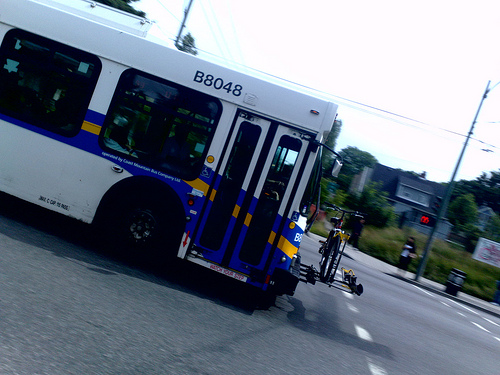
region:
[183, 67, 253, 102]
bus number on the side of the bus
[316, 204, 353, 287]
bike on the front of the bus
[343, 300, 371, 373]
white lines on the pavement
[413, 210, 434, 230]
pedestrian crossing sign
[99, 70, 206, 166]
window at the front of the bus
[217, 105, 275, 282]
doors on the bus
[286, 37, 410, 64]
sky is almost white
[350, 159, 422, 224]
buildings behind the sidewalk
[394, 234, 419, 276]
person is waiting at the corner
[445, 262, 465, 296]
paper box on the sidewalk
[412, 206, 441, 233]
cross walk signal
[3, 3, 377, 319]
bus driving down street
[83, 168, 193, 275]
front right bus wheel and tire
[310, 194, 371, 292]
bicycle on front of bus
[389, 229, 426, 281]
pedestrian waiting to cross street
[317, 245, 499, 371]
white stripes of cross walk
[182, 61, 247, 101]
bus ID number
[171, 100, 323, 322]
entry exit doors on bus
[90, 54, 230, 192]
window near front of bus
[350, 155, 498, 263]
house on side of street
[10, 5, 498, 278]
public transportation on a city street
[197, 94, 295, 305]
the door on the bus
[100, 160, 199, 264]
the wheel on the bus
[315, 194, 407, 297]
a bike rack on the bus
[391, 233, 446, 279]
a pedestrian waiting to cross the street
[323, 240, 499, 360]
a crosswalk for the person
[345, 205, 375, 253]
a person in the background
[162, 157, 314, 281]
the bus is yellow and blue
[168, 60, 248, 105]
the bus's ID number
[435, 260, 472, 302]
a stand near the corner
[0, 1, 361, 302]
A white, blue, and yellow bus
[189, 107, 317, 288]
A folding bus door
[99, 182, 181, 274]
The front tire of a bus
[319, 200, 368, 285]
A bike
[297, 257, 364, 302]
A bus rack on the front of a bus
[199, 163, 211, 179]
A blue and white handicap sign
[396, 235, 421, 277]
A person waiting to cross the street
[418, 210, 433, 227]
A cross walk signal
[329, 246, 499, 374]
A cross walk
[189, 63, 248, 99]
A bus identification number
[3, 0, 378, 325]
A bus in the foreground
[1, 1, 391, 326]
A bike in front of the bus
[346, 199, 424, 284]
People in the background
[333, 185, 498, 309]
Tall grass in the background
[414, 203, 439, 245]
Crosswalk light is on red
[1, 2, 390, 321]
The bus is white in color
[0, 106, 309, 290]
Bus has a blue and yellow stripe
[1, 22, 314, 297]
The windows are tinted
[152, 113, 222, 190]
Person inside the bus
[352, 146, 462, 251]
A house in the background